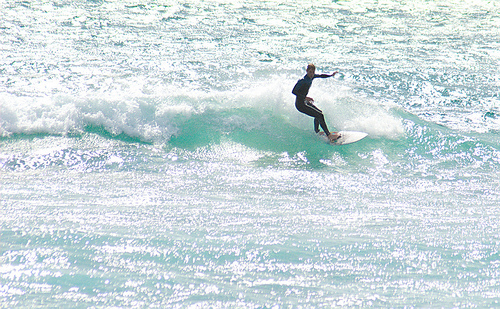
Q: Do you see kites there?
A: No, there are no kites.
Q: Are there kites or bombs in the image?
A: No, there are no kites or bombs.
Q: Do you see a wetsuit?
A: Yes, there is a wetsuit.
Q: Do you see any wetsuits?
A: Yes, there is a wetsuit.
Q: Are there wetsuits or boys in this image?
A: Yes, there is a wetsuit.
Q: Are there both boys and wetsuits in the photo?
A: No, there is a wetsuit but no boys.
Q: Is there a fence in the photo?
A: No, there are no fences.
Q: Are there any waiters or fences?
A: No, there are no fences or waiters.